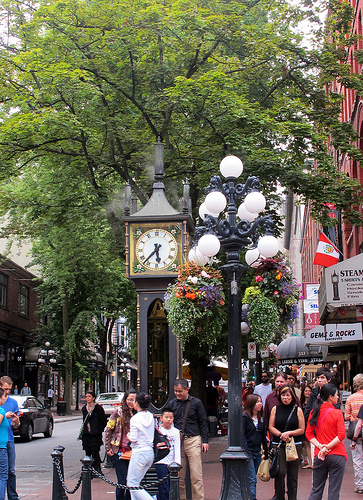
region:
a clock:
[128, 223, 189, 274]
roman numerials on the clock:
[137, 231, 150, 246]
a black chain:
[101, 473, 117, 488]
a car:
[22, 395, 60, 435]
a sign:
[306, 324, 359, 345]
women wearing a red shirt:
[319, 411, 347, 440]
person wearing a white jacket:
[130, 413, 153, 446]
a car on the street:
[95, 388, 117, 403]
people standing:
[260, 374, 354, 441]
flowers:
[183, 272, 220, 305]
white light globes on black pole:
[188, 157, 311, 447]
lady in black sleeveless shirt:
[245, 383, 313, 498]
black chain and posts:
[36, 438, 181, 499]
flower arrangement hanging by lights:
[160, 227, 240, 350]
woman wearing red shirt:
[302, 364, 361, 491]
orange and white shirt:
[341, 379, 361, 464]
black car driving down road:
[7, 376, 100, 443]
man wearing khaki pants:
[161, 370, 221, 495]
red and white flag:
[299, 228, 347, 285]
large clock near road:
[69, 127, 193, 498]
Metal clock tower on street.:
[121, 131, 195, 416]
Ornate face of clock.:
[128, 221, 181, 276]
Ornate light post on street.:
[187, 154, 278, 498]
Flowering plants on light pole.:
[160, 256, 304, 353]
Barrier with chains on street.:
[51, 444, 182, 498]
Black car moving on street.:
[0, 395, 53, 441]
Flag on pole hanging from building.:
[313, 229, 344, 267]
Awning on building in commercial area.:
[317, 251, 362, 325]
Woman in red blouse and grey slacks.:
[304, 382, 348, 498]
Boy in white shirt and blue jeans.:
[153, 408, 182, 499]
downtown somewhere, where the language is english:
[1, 1, 361, 498]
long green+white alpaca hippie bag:
[70, 399, 99, 438]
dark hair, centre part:
[268, 366, 290, 391]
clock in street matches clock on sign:
[117, 127, 343, 498]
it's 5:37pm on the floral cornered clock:
[129, 222, 183, 273]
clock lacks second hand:
[128, 219, 184, 275]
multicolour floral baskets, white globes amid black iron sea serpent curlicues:
[158, 150, 306, 360]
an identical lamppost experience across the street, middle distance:
[32, 337, 64, 418]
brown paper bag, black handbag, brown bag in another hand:
[252, 432, 299, 483]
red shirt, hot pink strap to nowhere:
[306, 402, 350, 462]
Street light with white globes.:
[183, 130, 280, 278]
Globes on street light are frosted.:
[182, 139, 281, 279]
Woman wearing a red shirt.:
[302, 376, 352, 499]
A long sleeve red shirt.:
[307, 384, 348, 464]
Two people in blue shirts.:
[0, 367, 23, 454]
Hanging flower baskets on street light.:
[171, 244, 299, 352]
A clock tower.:
[124, 131, 187, 428]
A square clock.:
[119, 204, 192, 281]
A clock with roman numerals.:
[124, 211, 187, 279]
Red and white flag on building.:
[314, 227, 342, 271]